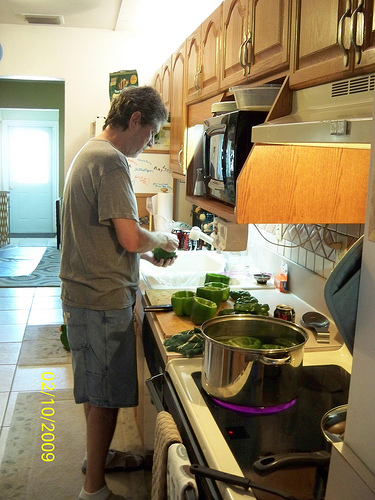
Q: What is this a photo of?
A: A man cooking.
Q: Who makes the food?
A: The chef.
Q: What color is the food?
A: Green.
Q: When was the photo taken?
A: Daytime.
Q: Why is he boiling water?
A: To cook the food.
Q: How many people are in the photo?
A: One.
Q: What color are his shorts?
A: Blue.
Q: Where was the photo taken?
A: In a kitchen.